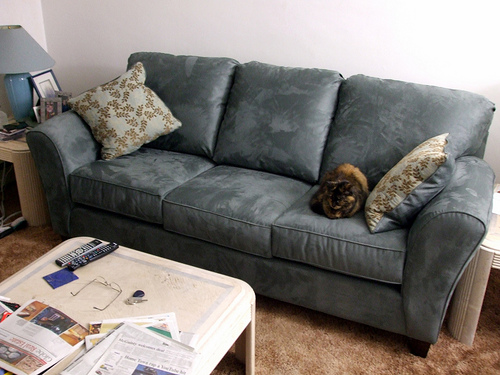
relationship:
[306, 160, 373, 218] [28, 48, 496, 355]
cat sitting on couch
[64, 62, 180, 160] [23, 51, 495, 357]
pillow on sofa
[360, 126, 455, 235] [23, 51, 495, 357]
pillow on sofa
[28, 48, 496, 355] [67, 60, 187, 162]
couch with matching pillows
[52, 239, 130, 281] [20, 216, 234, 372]
remote on table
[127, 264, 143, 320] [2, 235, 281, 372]
keys on table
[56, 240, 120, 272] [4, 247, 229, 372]
remote sitting on table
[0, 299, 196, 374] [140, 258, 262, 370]
newspaper on table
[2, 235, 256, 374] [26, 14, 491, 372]
table in living room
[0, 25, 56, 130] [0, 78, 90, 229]
lamp on table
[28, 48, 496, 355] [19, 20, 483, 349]
couch in living room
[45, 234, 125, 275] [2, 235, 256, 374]
remote controls on table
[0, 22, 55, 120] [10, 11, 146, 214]
lamp sitting in corner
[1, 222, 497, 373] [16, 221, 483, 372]
carpet across floor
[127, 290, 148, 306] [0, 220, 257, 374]
keys sitting on table top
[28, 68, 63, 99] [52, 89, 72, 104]
picture and flower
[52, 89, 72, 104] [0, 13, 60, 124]
flower next to lamp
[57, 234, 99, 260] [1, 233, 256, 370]
remote control on coffee table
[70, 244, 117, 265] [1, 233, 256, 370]
remote control on coffee table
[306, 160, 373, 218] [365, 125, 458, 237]
cat sitting next to a throw pillow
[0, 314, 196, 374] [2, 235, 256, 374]
newspaper on table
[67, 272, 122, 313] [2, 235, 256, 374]
eyeglasses on table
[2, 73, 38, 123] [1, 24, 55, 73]
lamp with lampshade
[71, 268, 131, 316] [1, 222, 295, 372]
glasses on table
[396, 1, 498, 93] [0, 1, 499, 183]
light reflection on wall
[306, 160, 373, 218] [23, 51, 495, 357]
cat sitting on sofa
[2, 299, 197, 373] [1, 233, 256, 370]
papers on coffee table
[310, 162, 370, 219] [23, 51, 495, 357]
cat sitting on sofa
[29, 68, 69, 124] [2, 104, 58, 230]
pictures sitting on end table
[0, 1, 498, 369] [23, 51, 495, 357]
living room has sofa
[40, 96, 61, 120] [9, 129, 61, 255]
picture on table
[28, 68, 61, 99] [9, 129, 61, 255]
picture on table